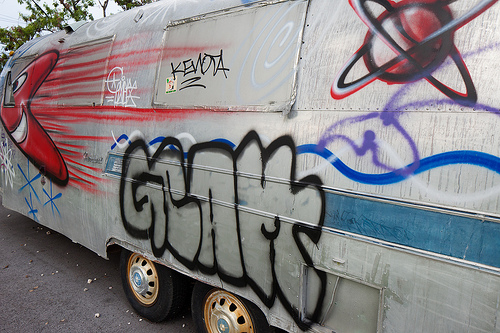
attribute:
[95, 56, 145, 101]
letters — white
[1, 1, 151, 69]
tree — green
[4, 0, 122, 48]
sky — light blue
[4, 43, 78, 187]
graffiti — red, white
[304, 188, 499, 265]
stripe — blue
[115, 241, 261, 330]
tires — black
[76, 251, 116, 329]
rocks — grey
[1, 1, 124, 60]
trees — green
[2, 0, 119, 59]
sky — grey, white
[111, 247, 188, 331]
wheel — black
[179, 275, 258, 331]
tire — black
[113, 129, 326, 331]
graffiti — black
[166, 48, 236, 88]
graffiti — black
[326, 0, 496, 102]
graffiti — black, red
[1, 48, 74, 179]
graffiti — red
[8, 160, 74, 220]
star graffiti — blue, on bus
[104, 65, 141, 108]
white handwriting — on bus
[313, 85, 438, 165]
purple writing — on bus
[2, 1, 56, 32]
green tree — above bus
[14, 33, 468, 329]
graffiti — on the vehicle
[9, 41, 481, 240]
graffiti — on the vehicle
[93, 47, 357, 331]
graffiti — on the vehicle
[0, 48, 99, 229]
graffiti — on the vehicle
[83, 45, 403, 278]
graffiti — on the vehicle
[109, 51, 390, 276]
graffiti — on the vehicle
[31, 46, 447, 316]
graffiti — on the vehicle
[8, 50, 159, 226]
graffiti — on the vehicle